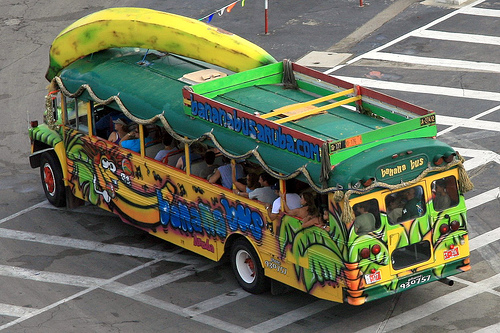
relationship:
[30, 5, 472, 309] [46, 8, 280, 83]
bus with banana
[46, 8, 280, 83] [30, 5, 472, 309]
banana on top of bus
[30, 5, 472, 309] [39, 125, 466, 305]
bus with paint